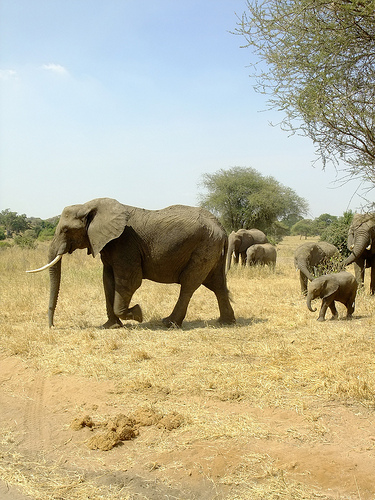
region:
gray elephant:
[33, 190, 234, 333]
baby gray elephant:
[302, 257, 354, 327]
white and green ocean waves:
[6, 13, 58, 63]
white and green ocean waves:
[167, 105, 198, 139]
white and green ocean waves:
[127, 135, 180, 186]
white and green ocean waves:
[118, 57, 210, 128]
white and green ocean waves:
[65, 134, 95, 172]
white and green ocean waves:
[95, 6, 147, 56]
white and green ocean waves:
[185, 96, 221, 151]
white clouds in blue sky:
[18, 35, 70, 71]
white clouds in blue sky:
[101, 29, 141, 81]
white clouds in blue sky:
[178, 97, 220, 129]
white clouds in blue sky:
[51, 148, 100, 186]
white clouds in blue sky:
[34, 69, 103, 124]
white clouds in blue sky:
[1, 118, 53, 172]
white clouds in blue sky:
[55, 51, 111, 88]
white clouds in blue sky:
[96, 48, 159, 81]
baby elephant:
[289, 264, 343, 339]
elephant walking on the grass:
[18, 200, 269, 336]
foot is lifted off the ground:
[123, 303, 148, 325]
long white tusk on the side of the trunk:
[20, 252, 73, 278]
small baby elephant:
[298, 270, 362, 319]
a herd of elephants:
[22, 171, 374, 340]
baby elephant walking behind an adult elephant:
[24, 196, 369, 336]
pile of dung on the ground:
[67, 405, 190, 452]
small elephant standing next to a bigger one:
[220, 225, 281, 268]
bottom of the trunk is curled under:
[300, 292, 322, 316]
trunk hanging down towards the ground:
[36, 247, 66, 330]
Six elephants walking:
[38, 191, 373, 334]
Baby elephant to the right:
[305, 269, 362, 322]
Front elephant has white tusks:
[25, 252, 63, 273]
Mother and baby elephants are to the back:
[228, 227, 278, 275]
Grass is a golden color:
[5, 252, 374, 387]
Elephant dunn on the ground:
[61, 408, 197, 452]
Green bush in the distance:
[200, 162, 302, 232]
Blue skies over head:
[5, 6, 300, 171]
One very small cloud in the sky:
[3, 65, 117, 105]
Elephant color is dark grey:
[39, 200, 246, 334]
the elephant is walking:
[18, 187, 241, 335]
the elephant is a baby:
[300, 265, 366, 325]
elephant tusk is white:
[25, 248, 73, 280]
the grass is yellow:
[1, 247, 373, 490]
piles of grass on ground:
[69, 405, 198, 463]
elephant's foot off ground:
[109, 303, 148, 329]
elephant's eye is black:
[57, 224, 79, 237]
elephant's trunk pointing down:
[42, 245, 72, 330]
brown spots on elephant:
[192, 238, 219, 273]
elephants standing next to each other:
[226, 216, 287, 271]